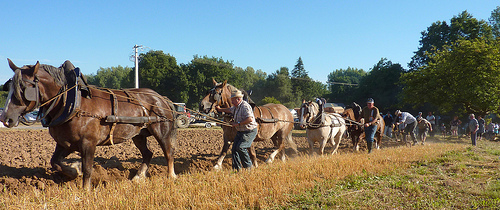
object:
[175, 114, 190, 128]
tire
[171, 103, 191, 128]
tractor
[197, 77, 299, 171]
horse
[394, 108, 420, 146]
man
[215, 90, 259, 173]
man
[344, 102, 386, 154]
horses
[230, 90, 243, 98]
hat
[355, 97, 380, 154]
man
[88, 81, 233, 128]
ropes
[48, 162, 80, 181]
foot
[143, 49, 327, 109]
trees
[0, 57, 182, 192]
brown horse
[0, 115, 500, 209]
field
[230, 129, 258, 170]
jeans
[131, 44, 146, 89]
electrical pole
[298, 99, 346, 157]
horse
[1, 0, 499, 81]
sky